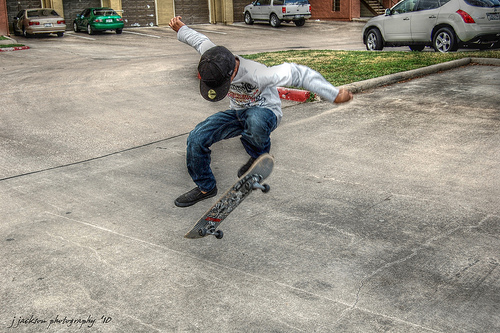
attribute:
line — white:
[123, 28, 160, 38]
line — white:
[66, 32, 95, 41]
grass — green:
[313, 53, 405, 68]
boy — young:
[149, 8, 366, 278]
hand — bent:
[277, 57, 366, 124]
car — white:
[362, 0, 497, 53]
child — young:
[167, 13, 352, 207]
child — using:
[158, 12, 275, 208]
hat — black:
[195, 47, 235, 102]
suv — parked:
[240, 0, 317, 30]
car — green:
[75, 10, 128, 41]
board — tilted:
[174, 152, 298, 251]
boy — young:
[158, 12, 360, 212]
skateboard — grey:
[176, 132, 289, 253]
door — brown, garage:
[117, 0, 157, 27]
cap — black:
[189, 44, 241, 103]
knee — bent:
[242, 118, 269, 143]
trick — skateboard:
[162, 134, 326, 238]